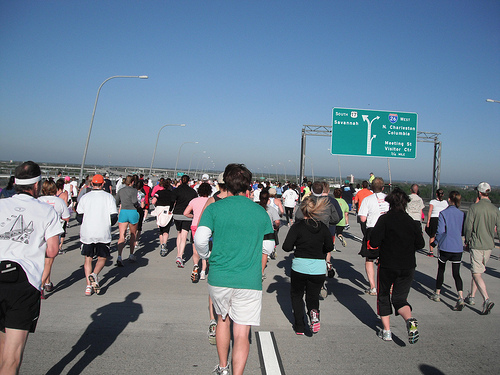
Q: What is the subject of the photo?
A: Marathon runners.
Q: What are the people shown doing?
A: Running.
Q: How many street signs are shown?
A: One.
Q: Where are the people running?
A: On freeway.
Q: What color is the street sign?
A: Green.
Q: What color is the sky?
A: Blue.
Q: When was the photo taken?
A: Daytime.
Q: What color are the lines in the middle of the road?
A: White.